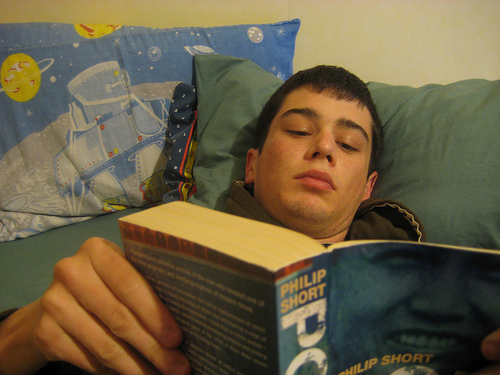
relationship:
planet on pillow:
[1, 52, 43, 105] [1, 22, 295, 243]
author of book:
[279, 267, 325, 316] [120, 200, 500, 375]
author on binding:
[279, 267, 325, 316] [277, 250, 329, 374]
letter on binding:
[283, 299, 328, 350] [277, 250, 329, 374]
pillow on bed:
[1, 22, 295, 243] [371, 80, 500, 249]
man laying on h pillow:
[244, 61, 383, 242] [367, 81, 500, 249]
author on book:
[279, 267, 325, 316] [120, 200, 500, 375]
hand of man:
[1, 236, 191, 374] [244, 61, 383, 242]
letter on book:
[285, 347, 328, 375] [120, 200, 500, 375]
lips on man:
[295, 169, 339, 193] [244, 61, 383, 242]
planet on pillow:
[72, 22, 124, 39] [1, 22, 295, 243]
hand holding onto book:
[1, 236, 191, 374] [120, 200, 500, 375]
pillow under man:
[367, 81, 500, 249] [244, 61, 383, 242]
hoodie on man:
[348, 197, 422, 243] [244, 61, 383, 242]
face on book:
[333, 242, 500, 365] [120, 200, 500, 375]